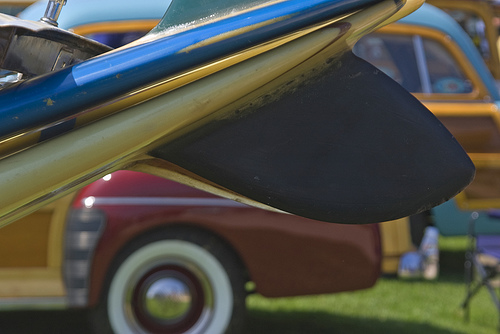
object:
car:
[0, 0, 500, 334]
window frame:
[340, 21, 490, 104]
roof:
[11, 0, 176, 29]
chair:
[459, 208, 500, 326]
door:
[366, 20, 500, 211]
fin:
[150, 49, 478, 225]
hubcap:
[144, 275, 193, 321]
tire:
[84, 221, 249, 334]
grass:
[246, 283, 500, 334]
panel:
[435, 114, 500, 153]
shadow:
[231, 304, 476, 334]